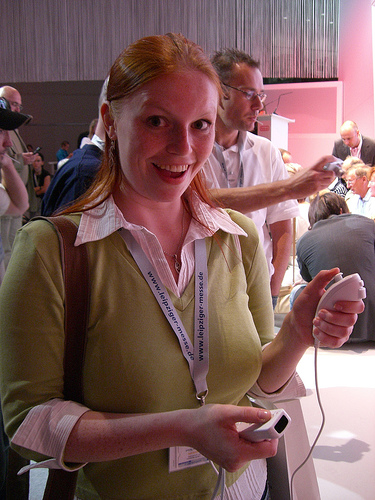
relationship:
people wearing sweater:
[0, 30, 365, 500] [3, 187, 272, 498]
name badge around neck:
[166, 441, 209, 474] [98, 162, 226, 348]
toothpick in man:
[246, 109, 267, 129] [197, 38, 308, 293]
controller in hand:
[304, 256, 366, 362] [292, 282, 363, 352]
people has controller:
[0, 30, 365, 500] [304, 256, 366, 362]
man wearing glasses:
[199, 48, 286, 308] [221, 80, 266, 105]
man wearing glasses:
[343, 162, 370, 214] [8, 99, 24, 111]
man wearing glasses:
[1, 86, 30, 260] [221, 80, 266, 105]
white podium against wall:
[270, 110, 291, 156] [270, 85, 333, 156]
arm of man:
[209, 178, 302, 212] [206, 34, 346, 211]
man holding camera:
[220, 46, 348, 282] [319, 153, 349, 183]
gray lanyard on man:
[218, 148, 248, 186] [212, 52, 302, 285]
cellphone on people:
[31, 144, 42, 155] [0, 30, 365, 500]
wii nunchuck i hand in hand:
[212, 271, 365, 498] [278, 271, 361, 349]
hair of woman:
[128, 48, 145, 77] [105, 35, 207, 89]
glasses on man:
[242, 89, 269, 107] [212, 37, 300, 297]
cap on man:
[2, 98, 31, 131] [4, 95, 31, 225]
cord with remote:
[288, 338, 325, 498] [233, 403, 302, 494]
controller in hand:
[311, 271, 369, 353] [291, 275, 363, 345]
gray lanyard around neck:
[115, 225, 211, 399] [118, 187, 193, 253]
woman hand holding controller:
[187, 400, 278, 472] [310, 282, 362, 348]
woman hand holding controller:
[290, 270, 366, 346] [310, 282, 362, 348]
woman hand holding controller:
[36, 182, 42, 190] [310, 282, 362, 348]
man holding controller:
[30, 149, 51, 197] [300, 284, 362, 342]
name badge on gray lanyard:
[166, 445, 223, 471] [115, 225, 211, 399]